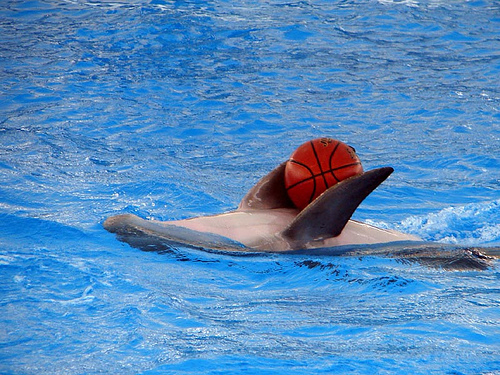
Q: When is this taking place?
A: Daytime.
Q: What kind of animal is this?
A: Dolphin.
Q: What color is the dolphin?
A: Grey.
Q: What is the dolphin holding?
A: Basketball.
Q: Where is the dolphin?
A: Water.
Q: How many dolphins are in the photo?
A: One.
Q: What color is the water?
A: Blue.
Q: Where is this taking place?
A: Aquarium.